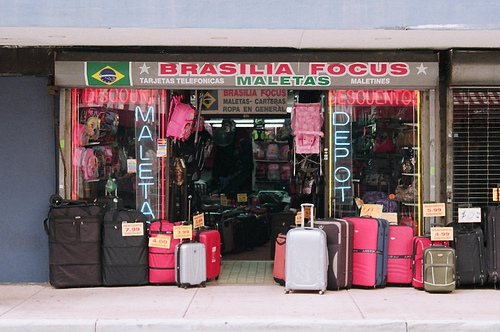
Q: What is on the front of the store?
A: A sign.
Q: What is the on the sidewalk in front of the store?
A: Luggage for sale.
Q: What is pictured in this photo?
A: A big brazilian luggage store.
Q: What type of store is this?
A: Luggage.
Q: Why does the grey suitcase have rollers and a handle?
A: So it can be pulled.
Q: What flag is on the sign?
A: Brazil.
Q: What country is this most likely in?
A: Brazil.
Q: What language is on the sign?
A: Spanish or portuguese.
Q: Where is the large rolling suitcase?
A: In front of the other suitcases.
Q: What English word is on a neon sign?
A: DISCOUNT.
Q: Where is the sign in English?
A: In the window under the flag.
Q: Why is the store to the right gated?
A: It's closed.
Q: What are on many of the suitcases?
A: Price tags.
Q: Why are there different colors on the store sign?
A: To get people's attention.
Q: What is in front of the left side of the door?
A: Suitcases.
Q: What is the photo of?
A: Store.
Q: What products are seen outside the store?
A: Luggage.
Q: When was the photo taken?
A: Daytime.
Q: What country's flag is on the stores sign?
A: Brazil.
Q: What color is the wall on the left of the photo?
A: Blue.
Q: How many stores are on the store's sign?
A: One.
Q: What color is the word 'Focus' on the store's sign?
A: Red.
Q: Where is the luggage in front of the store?
A: Sidewalk.